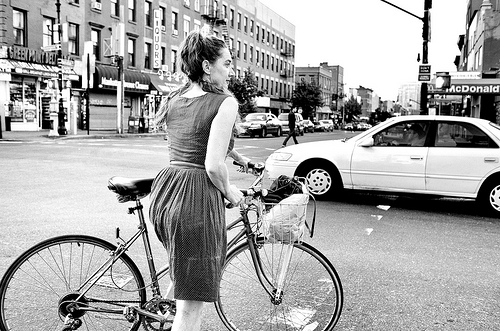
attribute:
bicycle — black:
[2, 158, 344, 330]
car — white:
[263, 115, 498, 221]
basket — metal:
[239, 177, 308, 245]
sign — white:
[152, 8, 161, 70]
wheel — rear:
[0, 233, 148, 331]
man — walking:
[285, 100, 299, 145]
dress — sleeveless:
[146, 88, 236, 302]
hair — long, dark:
[180, 29, 226, 93]